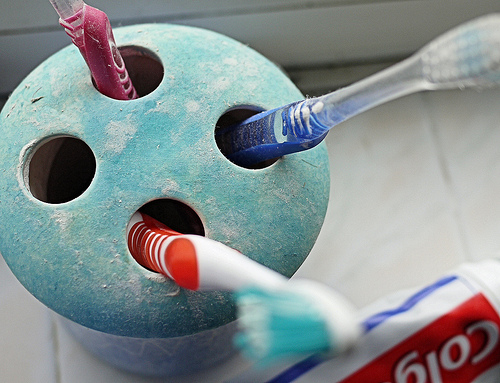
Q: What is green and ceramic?
A: Toothbrush holder.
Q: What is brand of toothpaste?
A: Colgate.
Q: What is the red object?
A: An adult toothbrush.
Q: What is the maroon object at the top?
A: An adult toothbrush.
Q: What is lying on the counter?
A: A tube of toothpaste.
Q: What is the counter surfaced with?
A: White tiles.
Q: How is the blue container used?
A: To store toothbrushes.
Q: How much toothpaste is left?
A: The tube is half full.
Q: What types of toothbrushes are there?
A: There are three adult sized toothbrushes.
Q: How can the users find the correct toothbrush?
A: Each one is a different color.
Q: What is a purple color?
A: A toothbrush.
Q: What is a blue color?
A: A toothbrush.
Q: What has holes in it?
A: Toothbrush holder.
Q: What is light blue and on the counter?
A: Toothbrush holder.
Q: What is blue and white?
A: Toothbrush bristles.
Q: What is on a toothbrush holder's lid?
A: Residue.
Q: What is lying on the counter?
A: Toothpaste tube.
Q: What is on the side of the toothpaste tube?
A: Brand name.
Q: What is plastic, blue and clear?
A: Toothbrush.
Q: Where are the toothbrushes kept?
A: In a contained with four holes on top.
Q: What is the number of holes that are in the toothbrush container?
A: Four.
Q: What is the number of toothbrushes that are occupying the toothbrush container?
A: Three.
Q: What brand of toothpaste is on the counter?
A: Colgate.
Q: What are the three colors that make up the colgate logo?
A: Red, white, and bie=e=lee.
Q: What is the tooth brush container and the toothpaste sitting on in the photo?
A: A white tiled counter.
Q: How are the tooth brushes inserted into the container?
A: Through holes in the lid.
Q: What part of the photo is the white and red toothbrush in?
A: Bottom-center.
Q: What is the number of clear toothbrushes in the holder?
A: Two.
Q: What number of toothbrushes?
A: Three.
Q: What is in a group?
A: Toothbrushes.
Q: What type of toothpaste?
A: Colgate.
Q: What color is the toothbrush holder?
A: Turquoise.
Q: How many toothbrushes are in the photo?
A: Three.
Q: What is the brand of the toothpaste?
A: Colgate.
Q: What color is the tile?
A: White.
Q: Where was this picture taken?
A: In a bathroom.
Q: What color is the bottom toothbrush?
A: Red.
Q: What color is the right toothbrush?
A: Blue.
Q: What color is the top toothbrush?
A: Pink.